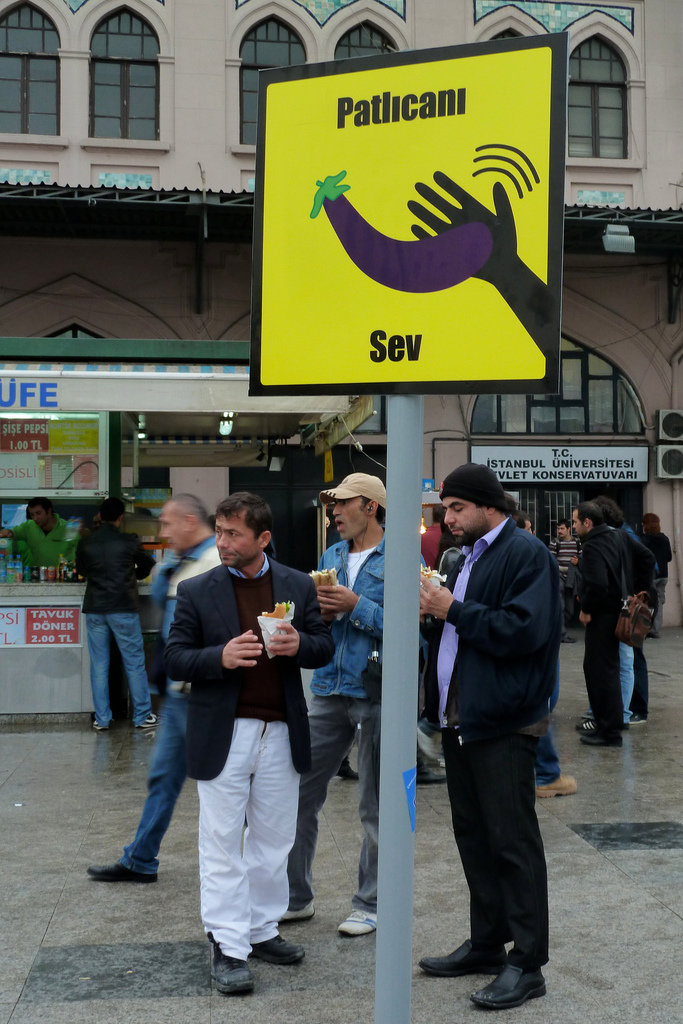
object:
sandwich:
[262, 600, 291, 619]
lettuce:
[282, 600, 291, 613]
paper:
[257, 600, 296, 658]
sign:
[26, 608, 80, 644]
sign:
[402, 762, 417, 833]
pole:
[374, 395, 424, 1019]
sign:
[471, 446, 649, 482]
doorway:
[519, 488, 579, 546]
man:
[573, 501, 624, 748]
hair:
[573, 501, 603, 528]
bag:
[615, 591, 652, 649]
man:
[418, 462, 562, 1009]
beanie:
[439, 462, 509, 512]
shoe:
[469, 963, 546, 1010]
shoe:
[418, 937, 507, 976]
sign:
[48, 421, 99, 454]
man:
[76, 496, 164, 729]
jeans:
[85, 613, 152, 726]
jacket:
[76, 521, 152, 612]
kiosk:
[0, 336, 350, 716]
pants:
[560, 577, 574, 635]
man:
[549, 518, 584, 642]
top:
[549, 536, 583, 575]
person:
[162, 492, 337, 995]